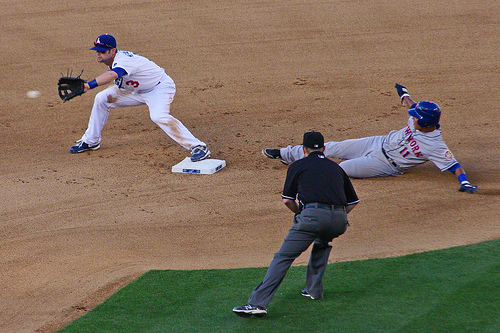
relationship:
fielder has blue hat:
[74, 83, 212, 173] [82, 99, 157, 126]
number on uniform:
[120, 78, 150, 99] [61, 29, 201, 162]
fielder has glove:
[56, 33, 211, 164] [49, 65, 88, 100]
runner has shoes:
[342, 92, 482, 195] [261, 141, 282, 160]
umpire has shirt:
[253, 141, 397, 305] [280, 157, 370, 212]